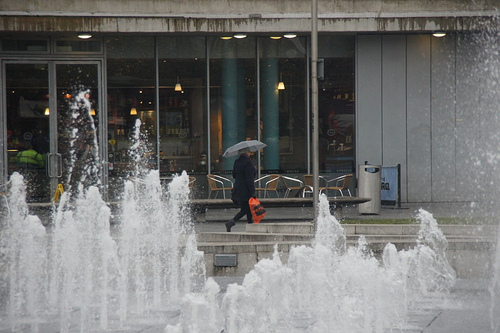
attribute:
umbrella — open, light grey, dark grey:
[221, 133, 267, 159]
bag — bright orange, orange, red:
[248, 192, 265, 225]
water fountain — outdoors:
[1, 85, 461, 331]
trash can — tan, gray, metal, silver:
[355, 162, 386, 215]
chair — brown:
[321, 169, 354, 204]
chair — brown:
[301, 171, 328, 201]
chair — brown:
[278, 171, 304, 200]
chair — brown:
[248, 167, 281, 202]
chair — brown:
[203, 171, 235, 200]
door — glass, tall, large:
[1, 56, 107, 210]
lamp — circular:
[275, 71, 287, 92]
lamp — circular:
[173, 76, 184, 95]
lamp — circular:
[129, 103, 138, 118]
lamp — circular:
[42, 104, 54, 116]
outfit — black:
[231, 155, 256, 224]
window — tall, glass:
[104, 33, 160, 202]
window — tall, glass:
[156, 30, 210, 201]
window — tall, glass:
[207, 31, 258, 200]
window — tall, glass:
[258, 35, 309, 195]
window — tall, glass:
[308, 31, 356, 202]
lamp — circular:
[89, 106, 96, 119]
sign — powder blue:
[364, 162, 402, 209]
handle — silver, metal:
[55, 152, 63, 181]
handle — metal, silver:
[44, 150, 55, 183]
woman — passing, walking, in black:
[224, 139, 261, 232]